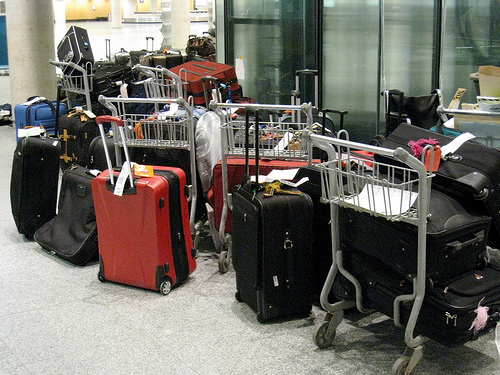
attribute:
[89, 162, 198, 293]
case — red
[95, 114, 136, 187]
handle — up, red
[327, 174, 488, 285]
bag — black, stacked, travelling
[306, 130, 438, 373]
cart — full, gray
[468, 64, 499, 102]
box — behind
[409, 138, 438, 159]
object — pink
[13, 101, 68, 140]
suitcase — blue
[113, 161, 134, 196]
badge — white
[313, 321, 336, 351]
wheel — black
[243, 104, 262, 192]
holder — black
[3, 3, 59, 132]
pillar — gray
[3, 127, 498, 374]
floor — gray